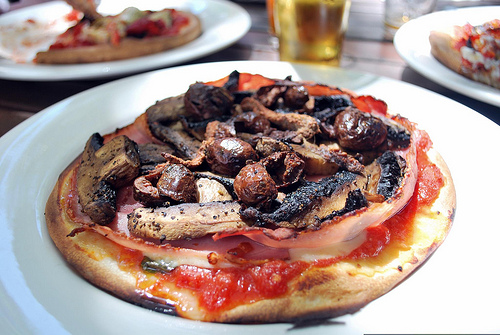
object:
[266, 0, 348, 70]
glass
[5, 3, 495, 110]
table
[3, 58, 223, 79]
rim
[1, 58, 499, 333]
plate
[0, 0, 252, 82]
plate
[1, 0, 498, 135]
table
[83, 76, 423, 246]
meat balls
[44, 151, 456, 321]
crust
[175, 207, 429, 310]
red sauce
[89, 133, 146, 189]
meat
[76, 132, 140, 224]
mushroom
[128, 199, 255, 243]
mushroom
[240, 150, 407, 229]
mushroom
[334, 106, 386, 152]
mushroom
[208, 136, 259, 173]
mushroom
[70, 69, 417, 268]
pizza toppings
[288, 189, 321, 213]
black decoration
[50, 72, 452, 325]
pizza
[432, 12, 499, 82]
pizza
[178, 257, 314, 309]
sauce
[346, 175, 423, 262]
sauce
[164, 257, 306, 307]
pizza patch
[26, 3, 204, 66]
pizza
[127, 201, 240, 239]
cumin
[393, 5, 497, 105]
plate